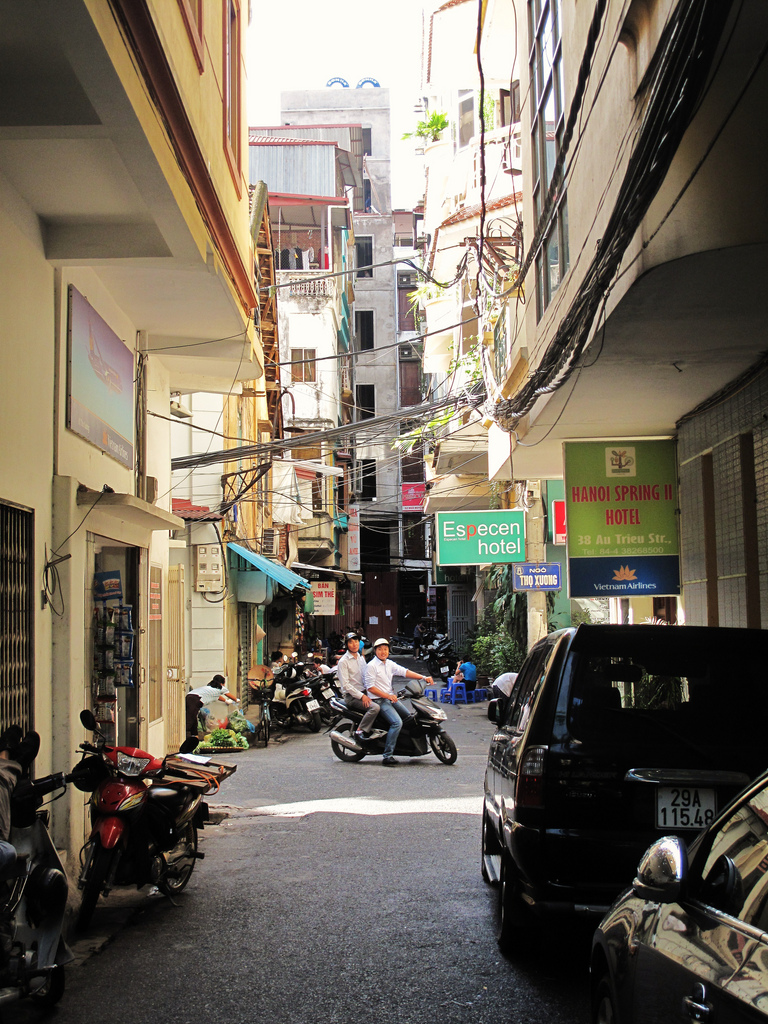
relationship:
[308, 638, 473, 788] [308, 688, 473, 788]
men on a motorbike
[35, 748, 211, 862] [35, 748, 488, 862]
motorbike parked on street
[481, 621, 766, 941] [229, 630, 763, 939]
van parked on street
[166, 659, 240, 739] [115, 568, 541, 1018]
woman on street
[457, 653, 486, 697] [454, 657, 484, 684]
woman wearing shirt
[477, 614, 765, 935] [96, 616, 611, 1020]
van on street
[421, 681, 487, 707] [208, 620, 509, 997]
chairs on road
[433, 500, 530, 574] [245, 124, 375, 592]
sign on building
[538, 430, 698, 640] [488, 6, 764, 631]
sign for hotel